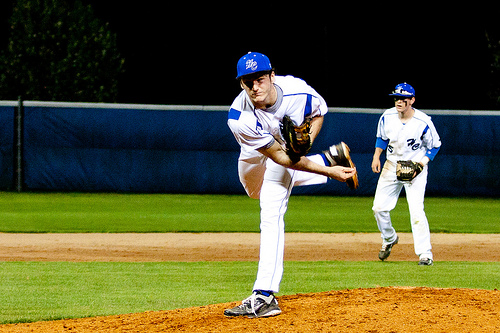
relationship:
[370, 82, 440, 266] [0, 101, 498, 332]
player on field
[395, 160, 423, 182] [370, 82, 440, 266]
mit on player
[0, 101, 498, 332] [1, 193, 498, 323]
field with grass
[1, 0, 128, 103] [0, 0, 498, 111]
tree behind net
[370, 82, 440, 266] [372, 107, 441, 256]
player wearing uniform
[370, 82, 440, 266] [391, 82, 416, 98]
player wearing hat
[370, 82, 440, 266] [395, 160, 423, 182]
player holding mit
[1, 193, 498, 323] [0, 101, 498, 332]
grass on a baseball field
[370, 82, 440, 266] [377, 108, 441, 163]
player wearing shirt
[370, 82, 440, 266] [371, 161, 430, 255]
man wearing pants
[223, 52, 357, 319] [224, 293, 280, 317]
player wearing sneaker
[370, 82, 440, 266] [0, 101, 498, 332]
player playing on field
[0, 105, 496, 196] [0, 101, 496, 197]
padding on fence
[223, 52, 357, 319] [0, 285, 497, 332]
player on mound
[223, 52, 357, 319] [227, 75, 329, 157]
player wearing jersey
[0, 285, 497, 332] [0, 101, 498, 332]
mound at baseball field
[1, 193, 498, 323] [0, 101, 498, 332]
grass of field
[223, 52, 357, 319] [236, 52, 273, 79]
player wearing cap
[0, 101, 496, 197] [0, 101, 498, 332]
fence of a baseball field